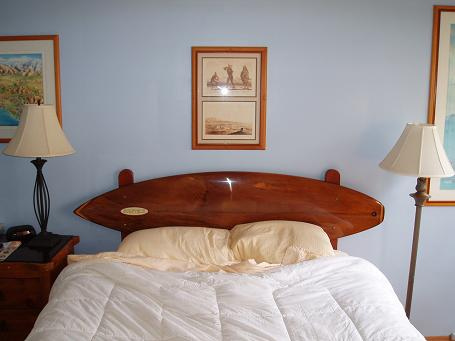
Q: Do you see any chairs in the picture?
A: No, there are no chairs.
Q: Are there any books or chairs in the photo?
A: No, there are no chairs or books.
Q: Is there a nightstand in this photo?
A: Yes, there is a nightstand.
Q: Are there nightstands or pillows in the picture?
A: Yes, there is a nightstand.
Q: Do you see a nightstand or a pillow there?
A: Yes, there is a nightstand.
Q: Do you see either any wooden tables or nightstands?
A: Yes, there is a wood nightstand.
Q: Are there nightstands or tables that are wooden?
A: Yes, the nightstand is wooden.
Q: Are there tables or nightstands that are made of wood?
A: Yes, the nightstand is made of wood.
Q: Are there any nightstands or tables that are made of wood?
A: Yes, the nightstand is made of wood.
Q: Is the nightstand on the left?
A: Yes, the nightstand is on the left of the image.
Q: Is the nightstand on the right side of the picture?
A: No, the nightstand is on the left of the image.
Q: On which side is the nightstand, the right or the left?
A: The nightstand is on the left of the image.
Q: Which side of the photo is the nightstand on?
A: The nightstand is on the left of the image.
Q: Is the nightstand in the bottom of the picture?
A: Yes, the nightstand is in the bottom of the image.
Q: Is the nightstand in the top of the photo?
A: No, the nightstand is in the bottom of the image.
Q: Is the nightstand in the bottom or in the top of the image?
A: The nightstand is in the bottom of the image.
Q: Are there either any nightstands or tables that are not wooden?
A: No, there is a nightstand but it is wooden.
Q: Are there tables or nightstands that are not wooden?
A: No, there is a nightstand but it is wooden.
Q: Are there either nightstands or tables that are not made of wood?
A: No, there is a nightstand but it is made of wood.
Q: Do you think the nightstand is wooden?
A: Yes, the nightstand is wooden.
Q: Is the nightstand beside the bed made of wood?
A: Yes, the nightstand is made of wood.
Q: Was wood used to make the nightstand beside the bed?
A: Yes, the nightstand is made of wood.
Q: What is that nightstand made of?
A: The nightstand is made of wood.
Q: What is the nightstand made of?
A: The nightstand is made of wood.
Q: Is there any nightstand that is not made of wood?
A: No, there is a nightstand but it is made of wood.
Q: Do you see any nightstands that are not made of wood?
A: No, there is a nightstand but it is made of wood.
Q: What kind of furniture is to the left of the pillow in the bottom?
A: The piece of furniture is a nightstand.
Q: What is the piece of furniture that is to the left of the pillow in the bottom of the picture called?
A: The piece of furniture is a nightstand.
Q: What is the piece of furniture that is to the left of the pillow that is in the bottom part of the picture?
A: The piece of furniture is a nightstand.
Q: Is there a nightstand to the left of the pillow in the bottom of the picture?
A: Yes, there is a nightstand to the left of the pillow.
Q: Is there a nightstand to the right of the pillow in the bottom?
A: No, the nightstand is to the left of the pillow.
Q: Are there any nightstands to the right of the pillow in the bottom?
A: No, the nightstand is to the left of the pillow.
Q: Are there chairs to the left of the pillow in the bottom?
A: No, there is a nightstand to the left of the pillow.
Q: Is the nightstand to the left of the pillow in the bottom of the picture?
A: Yes, the nightstand is to the left of the pillow.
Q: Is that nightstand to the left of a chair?
A: No, the nightstand is to the left of the pillow.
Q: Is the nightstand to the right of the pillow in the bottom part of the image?
A: No, the nightstand is to the left of the pillow.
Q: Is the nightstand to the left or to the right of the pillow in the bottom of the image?
A: The nightstand is to the left of the pillow.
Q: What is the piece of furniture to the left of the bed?
A: The piece of furniture is a nightstand.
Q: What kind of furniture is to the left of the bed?
A: The piece of furniture is a nightstand.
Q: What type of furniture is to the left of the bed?
A: The piece of furniture is a nightstand.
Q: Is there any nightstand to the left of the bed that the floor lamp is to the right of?
A: Yes, there is a nightstand to the left of the bed.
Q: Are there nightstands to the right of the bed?
A: No, the nightstand is to the left of the bed.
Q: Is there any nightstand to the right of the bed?
A: No, the nightstand is to the left of the bed.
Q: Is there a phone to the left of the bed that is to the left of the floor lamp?
A: No, there is a nightstand to the left of the bed.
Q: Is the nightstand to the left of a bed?
A: Yes, the nightstand is to the left of a bed.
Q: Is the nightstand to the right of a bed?
A: No, the nightstand is to the left of a bed.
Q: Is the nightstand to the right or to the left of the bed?
A: The nightstand is to the left of the bed.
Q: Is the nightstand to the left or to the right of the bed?
A: The nightstand is to the left of the bed.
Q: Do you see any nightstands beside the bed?
A: Yes, there is a nightstand beside the bed.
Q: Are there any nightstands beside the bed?
A: Yes, there is a nightstand beside the bed.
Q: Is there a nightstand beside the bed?
A: Yes, there is a nightstand beside the bed.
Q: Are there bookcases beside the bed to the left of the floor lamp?
A: No, there is a nightstand beside the bed.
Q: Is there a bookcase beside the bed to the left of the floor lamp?
A: No, there is a nightstand beside the bed.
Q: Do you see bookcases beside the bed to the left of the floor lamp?
A: No, there is a nightstand beside the bed.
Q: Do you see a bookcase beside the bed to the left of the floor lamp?
A: No, there is a nightstand beside the bed.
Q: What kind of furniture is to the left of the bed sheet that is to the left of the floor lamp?
A: The piece of furniture is a nightstand.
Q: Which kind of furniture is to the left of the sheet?
A: The piece of furniture is a nightstand.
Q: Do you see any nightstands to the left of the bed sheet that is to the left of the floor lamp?
A: Yes, there is a nightstand to the left of the sheet.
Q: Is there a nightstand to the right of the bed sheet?
A: No, the nightstand is to the left of the bed sheet.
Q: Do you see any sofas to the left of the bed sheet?
A: No, there is a nightstand to the left of the bed sheet.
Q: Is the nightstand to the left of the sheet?
A: Yes, the nightstand is to the left of the sheet.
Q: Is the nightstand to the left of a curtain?
A: No, the nightstand is to the left of the sheet.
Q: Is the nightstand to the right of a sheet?
A: No, the nightstand is to the left of a sheet.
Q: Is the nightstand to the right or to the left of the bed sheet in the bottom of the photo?
A: The nightstand is to the left of the sheet.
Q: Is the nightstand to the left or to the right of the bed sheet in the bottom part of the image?
A: The nightstand is to the left of the sheet.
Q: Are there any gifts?
A: No, there are no gifts.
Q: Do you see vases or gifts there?
A: No, there are no gifts or vases.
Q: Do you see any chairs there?
A: No, there are no chairs.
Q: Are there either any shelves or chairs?
A: No, there are no chairs or shelves.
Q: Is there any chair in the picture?
A: No, there are no chairs.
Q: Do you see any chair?
A: No, there are no chairs.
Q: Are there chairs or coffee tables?
A: No, there are no chairs or coffee tables.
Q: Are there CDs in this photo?
A: No, there are no cds.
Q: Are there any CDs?
A: No, there are no cds.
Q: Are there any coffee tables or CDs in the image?
A: No, there are no CDs or coffee tables.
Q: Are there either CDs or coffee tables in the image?
A: No, there are no CDs or coffee tables.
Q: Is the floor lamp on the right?
A: Yes, the floor lamp is on the right of the image.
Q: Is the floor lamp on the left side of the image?
A: No, the floor lamp is on the right of the image.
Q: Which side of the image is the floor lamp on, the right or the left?
A: The floor lamp is on the right of the image.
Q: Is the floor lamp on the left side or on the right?
A: The floor lamp is on the right of the image.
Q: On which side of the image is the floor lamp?
A: The floor lamp is on the right of the image.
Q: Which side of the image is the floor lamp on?
A: The floor lamp is on the right of the image.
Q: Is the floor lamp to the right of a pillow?
A: Yes, the floor lamp is to the right of a pillow.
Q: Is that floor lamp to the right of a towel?
A: No, the floor lamp is to the right of a pillow.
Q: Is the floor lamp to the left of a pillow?
A: No, the floor lamp is to the right of a pillow.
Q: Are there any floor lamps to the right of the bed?
A: Yes, there is a floor lamp to the right of the bed.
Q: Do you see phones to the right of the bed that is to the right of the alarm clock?
A: No, there is a floor lamp to the right of the bed.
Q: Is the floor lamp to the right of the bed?
A: Yes, the floor lamp is to the right of the bed.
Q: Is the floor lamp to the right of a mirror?
A: No, the floor lamp is to the right of the bed.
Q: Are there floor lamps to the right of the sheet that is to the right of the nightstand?
A: Yes, there is a floor lamp to the right of the sheet.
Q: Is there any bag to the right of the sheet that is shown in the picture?
A: No, there is a floor lamp to the right of the sheet.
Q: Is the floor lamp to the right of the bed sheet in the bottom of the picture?
A: Yes, the floor lamp is to the right of the sheet.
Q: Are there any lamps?
A: Yes, there is a lamp.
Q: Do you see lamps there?
A: Yes, there is a lamp.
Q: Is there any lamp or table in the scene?
A: Yes, there is a lamp.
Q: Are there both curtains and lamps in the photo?
A: No, there is a lamp but no curtains.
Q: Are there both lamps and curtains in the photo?
A: No, there is a lamp but no curtains.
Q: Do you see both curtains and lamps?
A: No, there is a lamp but no curtains.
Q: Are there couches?
A: No, there are no couches.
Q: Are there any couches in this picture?
A: No, there are no couches.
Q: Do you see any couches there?
A: No, there are no couches.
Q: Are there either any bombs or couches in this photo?
A: No, there are no couches or bombs.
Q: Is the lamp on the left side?
A: Yes, the lamp is on the left of the image.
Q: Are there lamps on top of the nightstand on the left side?
A: Yes, there is a lamp on top of the nightstand.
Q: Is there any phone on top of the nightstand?
A: No, there is a lamp on top of the nightstand.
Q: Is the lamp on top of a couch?
A: No, the lamp is on top of a nightstand.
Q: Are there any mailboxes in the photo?
A: No, there are no mailboxes.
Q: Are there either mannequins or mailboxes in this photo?
A: No, there are no mailboxes or mannequins.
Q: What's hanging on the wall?
A: The picture is hanging on the wall.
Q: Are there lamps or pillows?
A: Yes, there is a pillow.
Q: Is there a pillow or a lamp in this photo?
A: Yes, there is a pillow.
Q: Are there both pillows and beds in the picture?
A: Yes, there are both a pillow and a bed.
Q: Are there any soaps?
A: No, there are no soaps.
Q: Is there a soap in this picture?
A: No, there are no soaps.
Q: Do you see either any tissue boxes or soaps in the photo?
A: No, there are no soaps or tissue boxes.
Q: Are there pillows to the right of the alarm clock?
A: Yes, there is a pillow to the right of the alarm clock.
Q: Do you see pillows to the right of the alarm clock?
A: Yes, there is a pillow to the right of the alarm clock.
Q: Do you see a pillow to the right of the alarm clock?
A: Yes, there is a pillow to the right of the alarm clock.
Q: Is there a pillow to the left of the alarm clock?
A: No, the pillow is to the right of the alarm clock.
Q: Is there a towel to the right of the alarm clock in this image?
A: No, there is a pillow to the right of the alarm clock.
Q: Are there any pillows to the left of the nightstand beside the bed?
A: No, the pillow is to the right of the nightstand.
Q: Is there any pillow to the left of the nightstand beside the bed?
A: No, the pillow is to the right of the nightstand.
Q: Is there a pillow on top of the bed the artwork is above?
A: Yes, there is a pillow on top of the bed.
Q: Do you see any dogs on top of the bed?
A: No, there is a pillow on top of the bed.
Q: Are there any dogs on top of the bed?
A: No, there is a pillow on top of the bed.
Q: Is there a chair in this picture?
A: No, there are no chairs.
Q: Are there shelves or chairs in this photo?
A: No, there are no chairs or shelves.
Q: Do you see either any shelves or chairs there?
A: No, there are no chairs or shelves.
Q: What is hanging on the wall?
A: The picture is hanging on the wall.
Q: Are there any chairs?
A: No, there are no chairs.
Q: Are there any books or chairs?
A: No, there are no chairs or books.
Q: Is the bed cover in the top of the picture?
A: No, the bed cover is in the bottom of the image.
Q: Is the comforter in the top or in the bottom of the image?
A: The comforter is in the bottom of the image.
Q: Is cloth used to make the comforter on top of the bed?
A: Yes, the bed cover is made of cloth.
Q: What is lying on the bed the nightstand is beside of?
A: The comforter is lying on the bed.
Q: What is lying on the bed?
A: The comforter is lying on the bed.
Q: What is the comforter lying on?
A: The comforter is lying on the bed.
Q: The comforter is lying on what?
A: The comforter is lying on the bed.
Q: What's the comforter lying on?
A: The comforter is lying on the bed.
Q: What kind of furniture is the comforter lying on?
A: The comforter is lying on the bed.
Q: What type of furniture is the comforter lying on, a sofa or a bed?
A: The comforter is lying on a bed.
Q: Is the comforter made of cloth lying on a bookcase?
A: No, the quilt is lying on a bed.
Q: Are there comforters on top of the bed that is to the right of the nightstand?
A: Yes, there is a comforter on top of the bed.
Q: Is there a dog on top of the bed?
A: No, there is a comforter on top of the bed.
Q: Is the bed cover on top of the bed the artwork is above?
A: Yes, the bed cover is on top of the bed.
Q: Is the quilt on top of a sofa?
A: No, the quilt is on top of the bed.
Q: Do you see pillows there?
A: Yes, there is a pillow.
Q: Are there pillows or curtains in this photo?
A: Yes, there is a pillow.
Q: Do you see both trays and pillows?
A: No, there is a pillow but no trays.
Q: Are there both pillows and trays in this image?
A: No, there is a pillow but no trays.